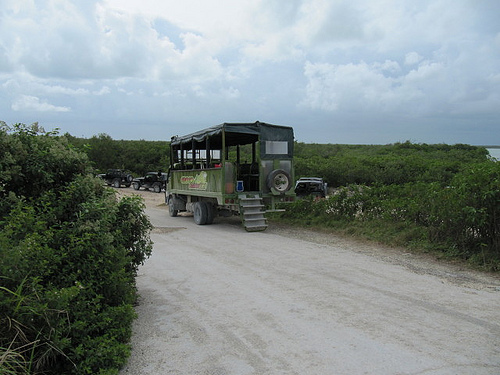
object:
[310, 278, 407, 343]
dirt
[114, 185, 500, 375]
concrete road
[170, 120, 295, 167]
top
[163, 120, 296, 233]
bus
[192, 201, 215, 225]
tire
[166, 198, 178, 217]
tire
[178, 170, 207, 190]
logo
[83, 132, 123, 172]
bush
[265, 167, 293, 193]
canteen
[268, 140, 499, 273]
bush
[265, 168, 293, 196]
tire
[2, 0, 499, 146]
clouds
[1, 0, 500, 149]
sky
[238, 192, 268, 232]
stairs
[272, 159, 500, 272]
tree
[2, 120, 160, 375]
bush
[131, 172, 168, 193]
car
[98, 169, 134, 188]
car